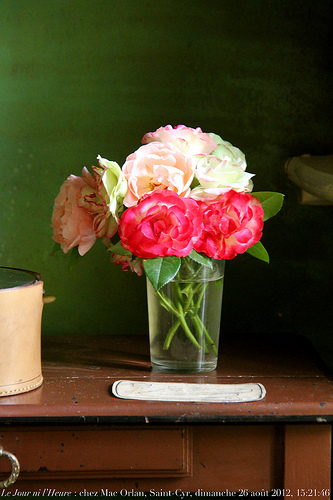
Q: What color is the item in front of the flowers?
A: White.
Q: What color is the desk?
A: Brown.